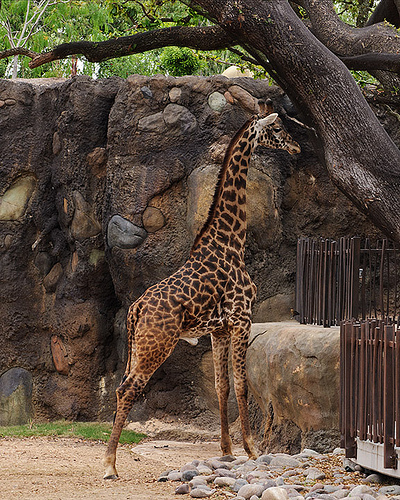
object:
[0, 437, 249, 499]
soil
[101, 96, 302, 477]
giraffe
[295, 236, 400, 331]
fence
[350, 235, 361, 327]
rails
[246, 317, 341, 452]
stone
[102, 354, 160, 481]
legs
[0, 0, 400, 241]
tree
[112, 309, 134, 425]
tail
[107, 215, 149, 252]
rock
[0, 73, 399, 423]
wall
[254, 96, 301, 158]
head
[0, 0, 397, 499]
zoo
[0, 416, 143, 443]
grass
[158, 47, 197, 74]
leaves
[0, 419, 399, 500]
ground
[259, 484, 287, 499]
stones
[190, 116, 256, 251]
hair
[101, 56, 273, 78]
area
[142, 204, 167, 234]
rocks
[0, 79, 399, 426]
pen